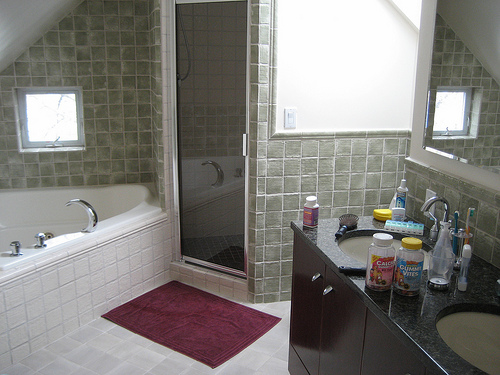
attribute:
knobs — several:
[289, 269, 340, 299]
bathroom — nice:
[0, 0, 497, 369]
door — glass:
[161, 15, 258, 307]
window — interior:
[10, 84, 90, 161]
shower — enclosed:
[166, 4, 308, 306]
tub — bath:
[2, 181, 165, 370]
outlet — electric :
[280, 104, 303, 138]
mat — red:
[118, 280, 283, 367]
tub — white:
[7, 179, 167, 329]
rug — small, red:
[102, 274, 286, 374]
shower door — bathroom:
[169, 2, 252, 279]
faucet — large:
[66, 190, 113, 230]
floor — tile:
[0, 278, 290, 373]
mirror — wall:
[419, 6, 497, 178]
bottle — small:
[365, 233, 393, 298]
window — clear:
[16, 82, 85, 154]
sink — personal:
[345, 220, 435, 273]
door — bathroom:
[176, 5, 253, 286]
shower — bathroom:
[168, 0, 419, 300]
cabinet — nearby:
[285, 224, 411, 372]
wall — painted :
[82, 38, 145, 180]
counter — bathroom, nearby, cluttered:
[291, 210, 494, 374]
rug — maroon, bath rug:
[102, 264, 288, 374]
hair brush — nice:
[333, 211, 361, 238]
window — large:
[11, 86, 83, 151]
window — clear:
[432, 87, 482, 139]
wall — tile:
[1, 0, 163, 203]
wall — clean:
[427, 14, 490, 161]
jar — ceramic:
[391, 236, 423, 298]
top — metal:
[400, 236, 423, 249]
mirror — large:
[398, 1, 499, 212]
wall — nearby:
[401, 8, 498, 228]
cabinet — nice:
[409, 295, 499, 366]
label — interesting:
[373, 223, 432, 332]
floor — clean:
[71, 255, 288, 375]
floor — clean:
[65, 306, 290, 375]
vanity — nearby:
[367, 267, 480, 344]